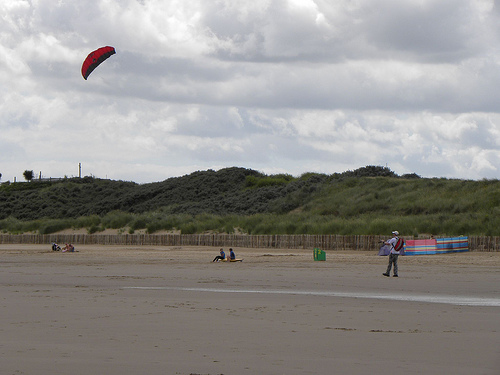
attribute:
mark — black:
[350, 316, 381, 340]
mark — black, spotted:
[200, 350, 209, 359]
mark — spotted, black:
[201, 350, 210, 357]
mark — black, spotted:
[208, 352, 223, 366]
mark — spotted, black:
[198, 350, 210, 359]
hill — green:
[0, 162, 484, 244]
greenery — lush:
[0, 211, 484, 231]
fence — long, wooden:
[1, 230, 484, 252]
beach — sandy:
[1, 240, 484, 371]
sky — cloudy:
[1, 0, 484, 183]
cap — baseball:
[390, 227, 400, 235]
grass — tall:
[2, 210, 225, 235]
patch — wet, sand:
[116, 282, 484, 308]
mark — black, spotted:
[319, 323, 357, 332]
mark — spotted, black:
[368, 325, 381, 334]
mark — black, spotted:
[369, 326, 402, 335]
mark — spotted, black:
[367, 326, 403, 334]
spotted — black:
[326, 323, 418, 339]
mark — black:
[368, 323, 395, 333]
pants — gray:
[382, 254, 398, 277]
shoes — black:
[377, 268, 400, 280]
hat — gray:
[390, 226, 404, 235]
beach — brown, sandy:
[6, 248, 498, 368]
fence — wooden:
[2, 224, 498, 251]